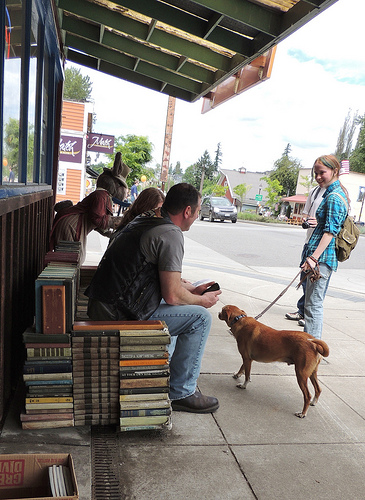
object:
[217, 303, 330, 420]
dog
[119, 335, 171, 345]
books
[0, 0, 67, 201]
window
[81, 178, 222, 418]
man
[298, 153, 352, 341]
girl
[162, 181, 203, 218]
hair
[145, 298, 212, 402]
trousers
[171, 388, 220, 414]
shoes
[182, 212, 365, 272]
street